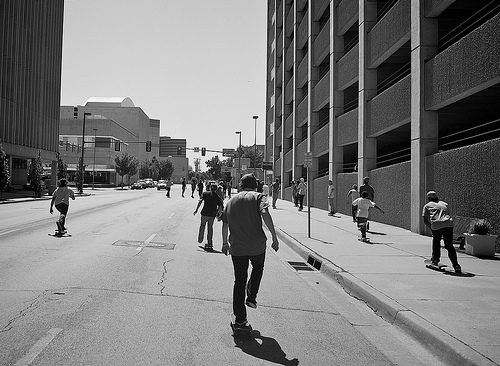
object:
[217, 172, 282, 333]
man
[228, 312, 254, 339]
skateboard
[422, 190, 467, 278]
man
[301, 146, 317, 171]
sign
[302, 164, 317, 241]
pole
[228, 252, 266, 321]
pants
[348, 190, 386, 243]
boy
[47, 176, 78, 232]
person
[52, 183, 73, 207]
shirt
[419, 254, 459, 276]
skateboard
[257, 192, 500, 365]
sidewalk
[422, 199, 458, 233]
shirt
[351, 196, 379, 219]
shirt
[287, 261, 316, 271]
drains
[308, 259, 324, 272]
ditch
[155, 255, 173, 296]
crack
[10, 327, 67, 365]
paint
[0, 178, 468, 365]
road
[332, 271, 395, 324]
crack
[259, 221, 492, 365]
curb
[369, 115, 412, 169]
window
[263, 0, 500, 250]
building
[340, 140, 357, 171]
window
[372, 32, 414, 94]
window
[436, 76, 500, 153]
window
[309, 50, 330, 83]
window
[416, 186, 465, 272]
person